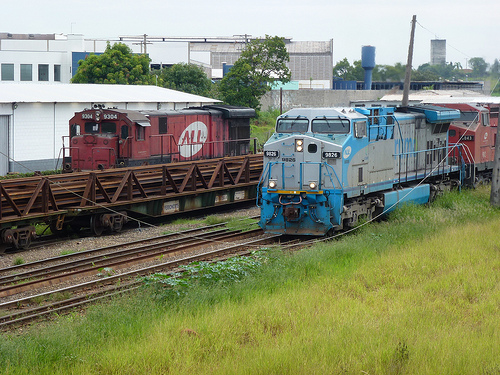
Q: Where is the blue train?
A: On tracks.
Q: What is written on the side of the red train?
A: All.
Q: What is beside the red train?
A: A building.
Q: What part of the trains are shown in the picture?
A: Engines.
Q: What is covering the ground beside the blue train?
A: Grass.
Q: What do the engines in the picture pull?
A: Cargo.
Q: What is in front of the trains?
A: Grass.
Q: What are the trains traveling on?
A: Track.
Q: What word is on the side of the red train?
A: All.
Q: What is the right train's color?
A: Grey and blue.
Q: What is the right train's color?
A: Red and black.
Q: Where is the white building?
A: Behind the red train.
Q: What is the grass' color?
A: Green.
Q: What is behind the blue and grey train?
A: Power pole.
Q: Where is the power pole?
A: Behind the right train.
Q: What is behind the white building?
A: Trees.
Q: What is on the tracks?
A: Blue and gray train.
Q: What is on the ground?
A: The large train track.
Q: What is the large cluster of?
A: Green trees.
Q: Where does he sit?
A: In the cab.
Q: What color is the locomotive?
A: Gray and blue.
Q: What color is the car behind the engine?
A: Maroon.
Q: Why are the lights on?
A: Safety.